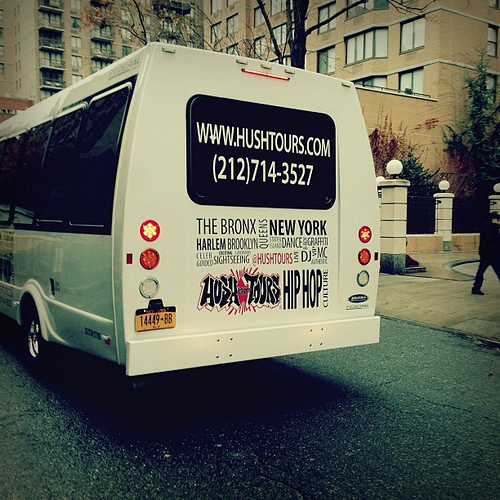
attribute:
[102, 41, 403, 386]
bus — white, back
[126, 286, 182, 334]
tag — yellow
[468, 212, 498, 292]
person — walking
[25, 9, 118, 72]
building — tan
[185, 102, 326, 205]
letters — white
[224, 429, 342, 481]
road — black, asphalt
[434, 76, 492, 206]
tree — tall, green, pine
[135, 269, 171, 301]
light — break light, white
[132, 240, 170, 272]
light — red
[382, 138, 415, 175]
lights — globe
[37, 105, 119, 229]
window — black, tinted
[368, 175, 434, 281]
post — cement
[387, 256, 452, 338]
sidewalk — gray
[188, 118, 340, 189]
advertisement — black